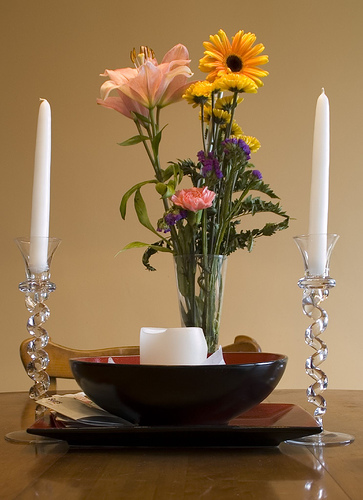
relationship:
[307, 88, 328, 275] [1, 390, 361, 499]
candle on table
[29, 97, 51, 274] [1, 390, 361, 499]
candle on table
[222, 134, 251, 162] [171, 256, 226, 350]
flower in vase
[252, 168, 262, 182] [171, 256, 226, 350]
flower in vase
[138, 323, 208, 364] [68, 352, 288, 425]
candle in bowl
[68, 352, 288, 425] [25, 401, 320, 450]
bowl on top of plate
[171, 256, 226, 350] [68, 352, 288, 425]
vase behind bowl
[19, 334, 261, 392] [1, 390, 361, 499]
chair behind table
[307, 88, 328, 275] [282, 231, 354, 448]
candle in candle holder